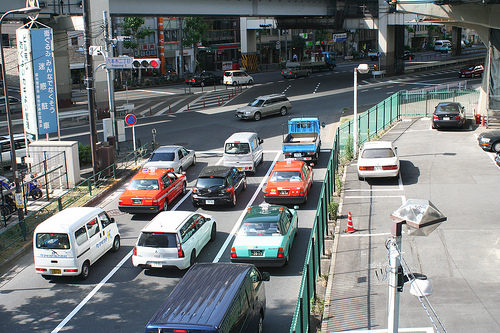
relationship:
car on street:
[357, 142, 399, 180] [313, 115, 498, 330]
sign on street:
[115, 111, 138, 131] [171, 188, 278, 270]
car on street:
[426, 96, 473, 141] [94, 151, 342, 272]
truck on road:
[283, 116, 326, 163] [0, 59, 341, 331]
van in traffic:
[29, 205, 123, 279] [147, 188, 274, 293]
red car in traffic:
[118, 168, 189, 214] [100, 179, 307, 322]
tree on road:
[6, 239, 66, 320] [0, 59, 341, 331]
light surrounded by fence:
[349, 59, 370, 155] [288, 94, 406, 328]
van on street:
[34, 206, 123, 280] [26, 65, 338, 331]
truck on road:
[279, 113, 326, 162] [144, 95, 282, 318]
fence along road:
[283, 77, 470, 328] [0, 59, 341, 331]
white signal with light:
[107, 50, 160, 69] [150, 60, 158, 67]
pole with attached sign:
[1, 46, 44, 251] [5, 172, 30, 222]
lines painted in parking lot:
[340, 224, 394, 243] [337, 185, 389, 275]